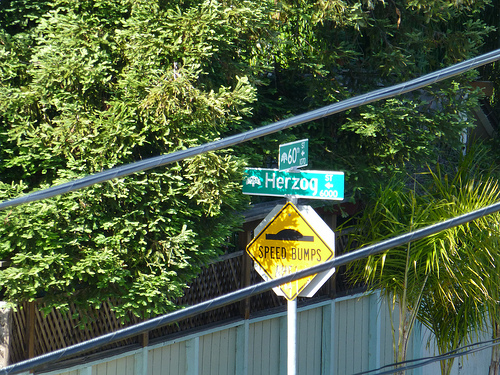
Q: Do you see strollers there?
A: No, there are no strollers.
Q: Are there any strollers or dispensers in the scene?
A: No, there are no strollers or dispensers.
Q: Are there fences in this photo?
A: Yes, there is a fence.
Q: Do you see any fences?
A: Yes, there is a fence.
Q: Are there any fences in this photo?
A: Yes, there is a fence.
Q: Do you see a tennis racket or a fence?
A: Yes, there is a fence.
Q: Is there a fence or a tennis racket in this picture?
A: Yes, there is a fence.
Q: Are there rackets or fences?
A: Yes, there is a fence.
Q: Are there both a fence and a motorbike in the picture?
A: No, there is a fence but no motorcycles.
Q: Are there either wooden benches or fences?
A: Yes, there is a wood fence.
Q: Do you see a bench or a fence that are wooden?
A: Yes, the fence is wooden.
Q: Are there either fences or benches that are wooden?
A: Yes, the fence is wooden.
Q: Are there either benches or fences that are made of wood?
A: Yes, the fence is made of wood.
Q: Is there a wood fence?
A: Yes, there is a fence that is made of wood.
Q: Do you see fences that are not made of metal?
A: Yes, there is a fence that is made of wood.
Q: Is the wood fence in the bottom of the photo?
A: Yes, the fence is in the bottom of the image.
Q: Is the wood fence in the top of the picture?
A: No, the fence is in the bottom of the image.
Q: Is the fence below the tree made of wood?
A: Yes, the fence is made of wood.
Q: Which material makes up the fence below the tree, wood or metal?
A: The fence is made of wood.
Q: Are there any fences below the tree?
A: Yes, there is a fence below the tree.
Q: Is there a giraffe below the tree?
A: No, there is a fence below the tree.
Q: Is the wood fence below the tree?
A: Yes, the fence is below the tree.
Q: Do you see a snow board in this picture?
A: No, there are no snowboards.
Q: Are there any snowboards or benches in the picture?
A: No, there are no snowboards or benches.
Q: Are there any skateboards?
A: No, there are no skateboards.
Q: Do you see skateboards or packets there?
A: No, there are no skateboards or packets.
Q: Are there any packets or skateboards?
A: No, there are no skateboards or packets.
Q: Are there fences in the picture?
A: Yes, there is a fence.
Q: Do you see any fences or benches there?
A: Yes, there is a fence.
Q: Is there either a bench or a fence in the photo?
A: Yes, there is a fence.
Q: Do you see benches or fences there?
A: Yes, there is a fence.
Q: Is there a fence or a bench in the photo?
A: Yes, there is a fence.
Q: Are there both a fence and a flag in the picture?
A: No, there is a fence but no flags.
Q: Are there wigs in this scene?
A: No, there are no wigs.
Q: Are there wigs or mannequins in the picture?
A: No, there are no wigs or mannequins.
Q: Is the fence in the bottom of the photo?
A: Yes, the fence is in the bottom of the image.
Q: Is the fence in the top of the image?
A: No, the fence is in the bottom of the image.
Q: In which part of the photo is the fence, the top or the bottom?
A: The fence is in the bottom of the image.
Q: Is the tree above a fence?
A: Yes, the tree is above a fence.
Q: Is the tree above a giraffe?
A: No, the tree is above a fence.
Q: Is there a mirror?
A: No, there are no mirrors.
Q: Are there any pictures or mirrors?
A: No, there are no mirrors or pictures.